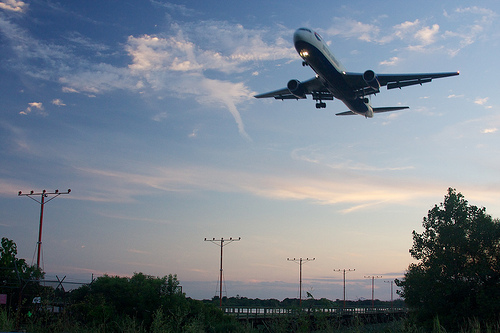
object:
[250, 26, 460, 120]
airplane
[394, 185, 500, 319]
tree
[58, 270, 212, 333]
bushes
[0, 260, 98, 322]
fence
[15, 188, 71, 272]
pole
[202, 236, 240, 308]
pole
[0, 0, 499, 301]
sky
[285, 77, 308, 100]
engine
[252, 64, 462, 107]
wingspan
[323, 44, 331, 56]
windows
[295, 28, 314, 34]
windshield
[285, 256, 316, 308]
pole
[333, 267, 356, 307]
pole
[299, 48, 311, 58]
light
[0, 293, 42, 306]
train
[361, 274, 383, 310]
pole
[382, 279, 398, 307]
pole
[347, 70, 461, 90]
wing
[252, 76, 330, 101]
wing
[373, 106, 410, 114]
tail wing